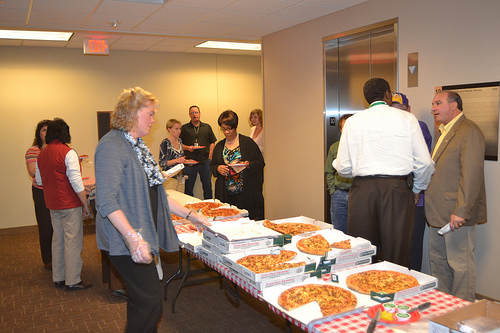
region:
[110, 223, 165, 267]
A clear plastic glove.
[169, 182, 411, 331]
Pizzas on a table.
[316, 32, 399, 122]
Silver elevator doors.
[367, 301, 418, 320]
A red plate with sauce.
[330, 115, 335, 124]
Floor number on elevator.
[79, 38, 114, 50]
A red and white Exit sign.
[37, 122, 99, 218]
A woman wearing a red vest.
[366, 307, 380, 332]
A knife leaning on plate.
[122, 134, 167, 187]
A black and white floral scarf.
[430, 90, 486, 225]
A man wearing a sports jacket.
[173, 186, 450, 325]
Pizza on the tables.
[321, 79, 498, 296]
Four men in a group.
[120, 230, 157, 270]
Woman with plastic glove on.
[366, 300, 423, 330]
Dipping sauces on a plate.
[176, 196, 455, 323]
White pizza boxes with pizza.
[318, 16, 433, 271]
Elevator behind the men.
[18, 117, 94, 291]
Women talking to each other.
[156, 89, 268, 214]
Group of people waiting to eat.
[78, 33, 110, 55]
Exit sign on the ceiling.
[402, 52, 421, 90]
Sign to signal arrival of elevator.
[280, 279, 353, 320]
a round pizza pie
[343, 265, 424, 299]
a round pizza pie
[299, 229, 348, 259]
a round pizza pie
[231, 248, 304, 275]
a round pizza pie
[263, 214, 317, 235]
a round pizza pie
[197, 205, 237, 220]
a round pizza pie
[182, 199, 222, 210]
a round pizza pie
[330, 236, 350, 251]
a slice of pizza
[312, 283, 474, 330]
a red and white checkered tablecloth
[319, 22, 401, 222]
a closed elevator door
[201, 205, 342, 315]
plenty pizzas are visible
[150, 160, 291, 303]
plenty pizzas are visible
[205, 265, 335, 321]
plenty pizzas are visible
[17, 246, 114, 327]
the floor is wooden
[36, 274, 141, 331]
the floor is wooden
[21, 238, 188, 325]
the floor is wooden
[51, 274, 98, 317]
the floor is wooden